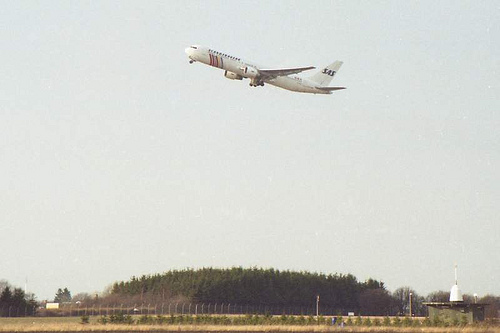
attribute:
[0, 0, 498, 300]
clouds — are white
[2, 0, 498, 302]
sky — is white, is blue, cloudless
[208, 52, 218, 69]
stripes — red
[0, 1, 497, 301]
overcast — day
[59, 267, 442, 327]
fence — long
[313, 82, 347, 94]
wing — small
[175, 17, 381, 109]
airplane — blue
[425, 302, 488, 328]
green building — small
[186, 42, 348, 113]
plane — taking off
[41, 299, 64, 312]
building — small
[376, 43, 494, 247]
sky — is blue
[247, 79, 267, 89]
landing gear — down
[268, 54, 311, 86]
wing — big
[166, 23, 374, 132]
jet — taking off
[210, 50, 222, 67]
stripe — blue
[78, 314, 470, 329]
bushes — are small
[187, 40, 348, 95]
plane — is white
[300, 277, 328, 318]
light — street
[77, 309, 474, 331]
trees — small, green, pine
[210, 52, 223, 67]
stripes — red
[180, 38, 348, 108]
airplane — white